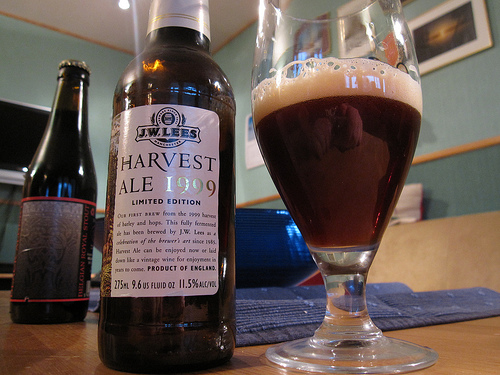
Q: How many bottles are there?
A: Two.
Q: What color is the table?
A: Brown.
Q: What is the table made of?
A: Wood.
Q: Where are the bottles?
A: On the table.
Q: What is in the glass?
A: Beer.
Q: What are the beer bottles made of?
A: Glass.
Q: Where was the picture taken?
A: In a kitchen.